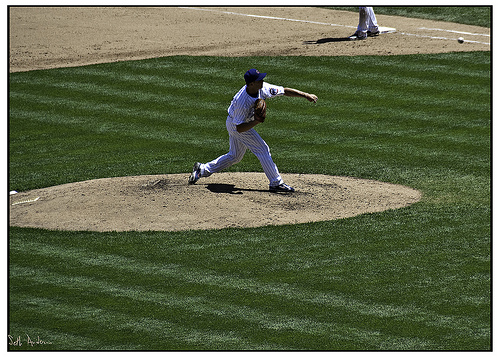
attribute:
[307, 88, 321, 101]
hand — player's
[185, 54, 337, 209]
uniform — white, Chicago Cubs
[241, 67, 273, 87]
cap — Blue, Chicago Cubs, baseball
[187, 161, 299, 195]
shoes — blue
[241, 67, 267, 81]
hat — blue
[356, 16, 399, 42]
first base — white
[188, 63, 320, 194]
man — baseball player, extending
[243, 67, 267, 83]
cap — blue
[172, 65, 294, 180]
pitcher — dirt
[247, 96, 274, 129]
mitt — catchers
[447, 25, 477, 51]
baseball — in the air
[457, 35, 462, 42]
baseball — flying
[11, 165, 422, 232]
dirt — brown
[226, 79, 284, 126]
shirt — pitcher's 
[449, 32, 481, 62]
baseball — white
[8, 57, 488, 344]
grass — green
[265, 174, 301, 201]
shoe — black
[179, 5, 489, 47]
lines — white, painted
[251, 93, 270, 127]
glove — leather, brown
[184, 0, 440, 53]
line — white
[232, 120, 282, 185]
stripes — blue